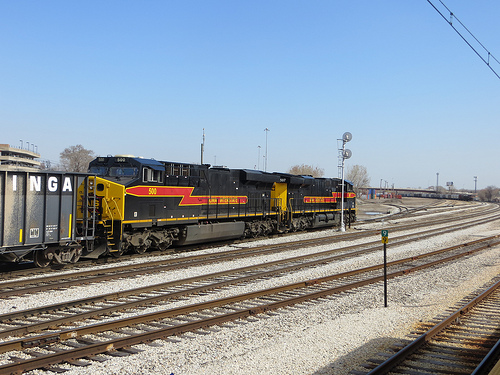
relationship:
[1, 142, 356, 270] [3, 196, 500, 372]
train on tracks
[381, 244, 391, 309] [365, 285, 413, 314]
pole in rocks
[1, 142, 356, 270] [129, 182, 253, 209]
train has stripe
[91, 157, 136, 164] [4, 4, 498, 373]
lights in photo